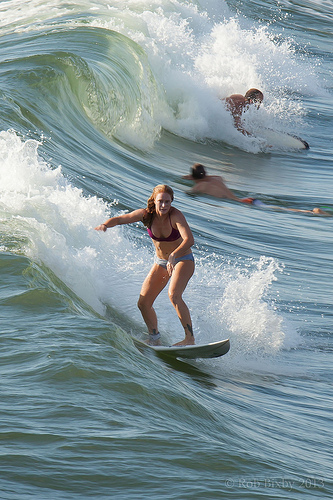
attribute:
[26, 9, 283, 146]
ocean — white and green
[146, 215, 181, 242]
bikini top — purple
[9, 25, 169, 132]
ocean waves — white, green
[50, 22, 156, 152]
waves — green, white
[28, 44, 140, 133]
waves — white, green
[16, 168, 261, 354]
waves — white, green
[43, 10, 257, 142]
waves — green, white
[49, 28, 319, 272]
waves — white and green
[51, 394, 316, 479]
water — greenish blue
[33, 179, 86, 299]
waves — green, white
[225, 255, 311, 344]
waves — white, green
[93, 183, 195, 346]
girl — pantless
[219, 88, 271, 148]
man — surfing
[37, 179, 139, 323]
foam — white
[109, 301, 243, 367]
surfboard — white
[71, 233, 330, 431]
waves — white and green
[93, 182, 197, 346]
person — surfing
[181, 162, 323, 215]
person — surfing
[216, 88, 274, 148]
person — surfing